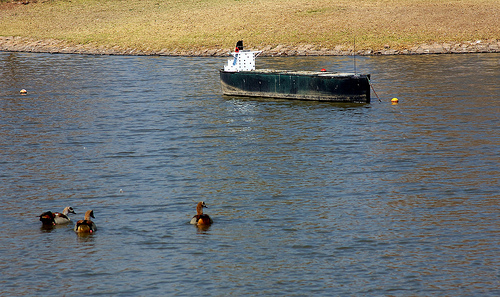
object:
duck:
[188, 194, 218, 232]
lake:
[8, 50, 495, 295]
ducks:
[32, 199, 106, 242]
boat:
[212, 30, 381, 110]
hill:
[2, 4, 498, 53]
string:
[366, 74, 391, 108]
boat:
[213, 37, 373, 111]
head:
[193, 197, 209, 211]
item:
[13, 83, 29, 95]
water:
[148, 159, 275, 279]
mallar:
[72, 206, 101, 235]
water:
[22, 172, 149, 272]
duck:
[35, 203, 78, 226]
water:
[24, 175, 156, 273]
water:
[10, 54, 490, 295]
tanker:
[213, 34, 378, 112]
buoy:
[384, 90, 402, 110]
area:
[4, 4, 498, 51]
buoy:
[15, 83, 33, 95]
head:
[193, 197, 209, 215]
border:
[12, 37, 499, 58]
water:
[266, 117, 482, 260]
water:
[104, 112, 185, 186]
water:
[194, 115, 455, 242]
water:
[263, 123, 377, 250]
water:
[313, 130, 443, 234]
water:
[268, 171, 366, 264]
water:
[268, 186, 381, 292]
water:
[286, 145, 446, 239]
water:
[293, 158, 472, 265]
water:
[286, 171, 452, 272]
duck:
[151, 185, 257, 247]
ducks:
[50, 161, 262, 278]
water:
[223, 148, 397, 245]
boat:
[194, 24, 424, 142]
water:
[273, 152, 435, 250]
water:
[254, 144, 433, 277]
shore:
[29, 24, 175, 105]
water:
[203, 131, 442, 234]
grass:
[85, 3, 209, 56]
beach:
[28, 6, 215, 92]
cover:
[219, 30, 276, 95]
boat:
[203, 24, 399, 135]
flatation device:
[373, 73, 422, 119]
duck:
[37, 180, 98, 242]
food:
[83, 10, 259, 210]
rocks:
[366, 22, 483, 81]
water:
[270, 139, 464, 261]